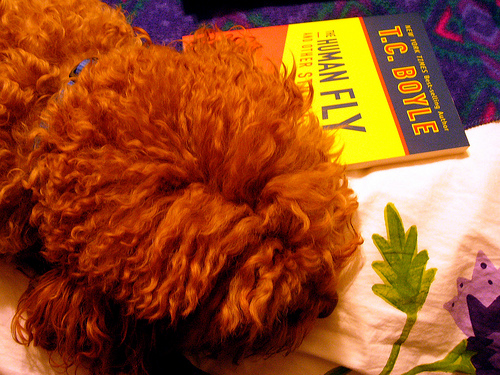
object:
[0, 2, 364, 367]
dog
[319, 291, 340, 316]
nose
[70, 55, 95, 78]
collar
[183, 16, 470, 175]
book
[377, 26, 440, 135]
t c boyle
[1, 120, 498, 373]
sheet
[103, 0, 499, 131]
shawl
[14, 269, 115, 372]
ear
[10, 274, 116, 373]
hair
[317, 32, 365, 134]
title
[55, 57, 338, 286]
top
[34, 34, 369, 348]
head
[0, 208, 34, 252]
paw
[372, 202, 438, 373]
leaf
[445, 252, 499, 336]
flower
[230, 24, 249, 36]
hair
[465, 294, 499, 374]
portion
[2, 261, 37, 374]
part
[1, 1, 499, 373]
bed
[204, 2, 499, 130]
pattern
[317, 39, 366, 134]
human fly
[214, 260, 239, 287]
eye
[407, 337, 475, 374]
green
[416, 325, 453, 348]
white